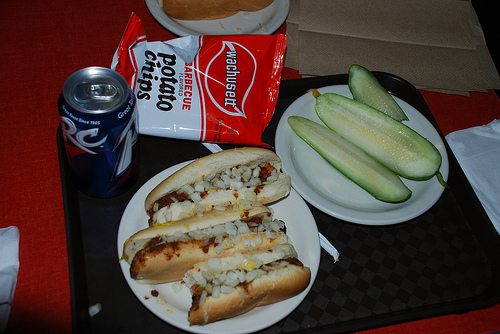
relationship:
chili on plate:
[145, 290, 165, 300] [115, 159, 322, 334]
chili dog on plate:
[124, 208, 296, 282] [115, 159, 322, 334]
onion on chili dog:
[169, 218, 261, 239] [124, 208, 296, 282]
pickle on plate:
[285, 115, 446, 205] [274, 83, 451, 229]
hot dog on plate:
[141, 146, 292, 227] [115, 159, 322, 334]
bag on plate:
[108, 12, 288, 150] [274, 85, 449, 226]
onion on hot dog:
[193, 165, 265, 188] [141, 146, 292, 227]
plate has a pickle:
[274, 83, 451, 229] [285, 115, 446, 205]